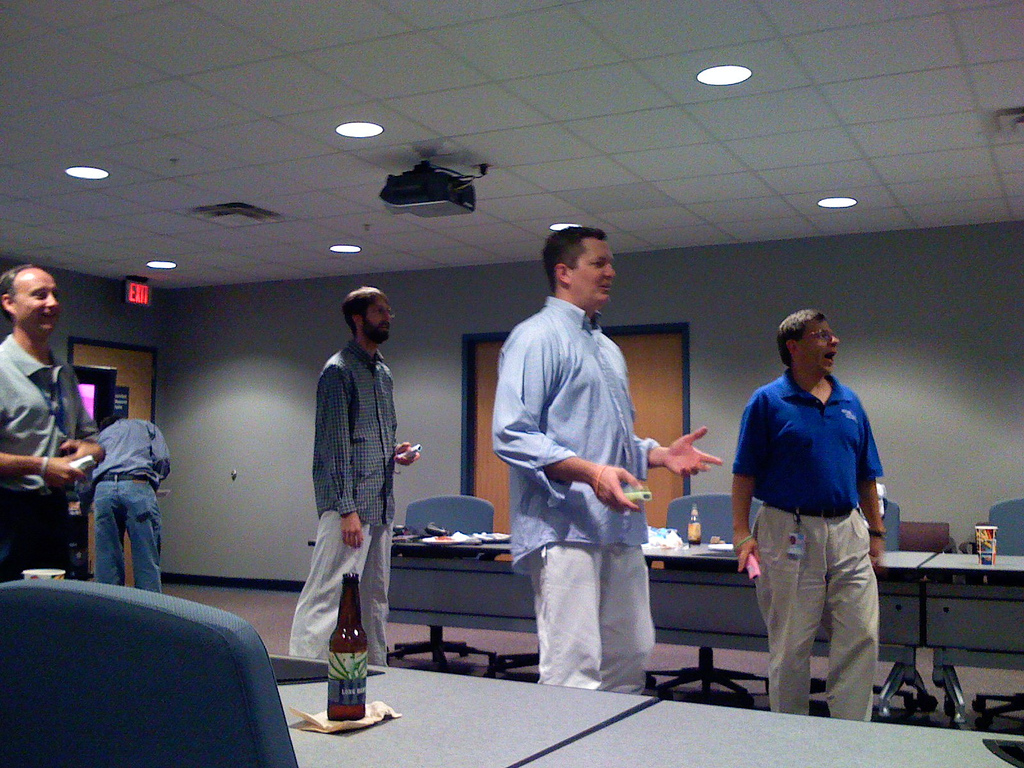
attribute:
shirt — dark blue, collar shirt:
[732, 376, 881, 517]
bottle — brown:
[324, 570, 364, 720]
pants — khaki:
[752, 508, 880, 717]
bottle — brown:
[325, 575, 368, 718]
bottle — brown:
[330, 575, 366, 718]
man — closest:
[90, 420, 170, 592]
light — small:
[697, 59, 756, 94]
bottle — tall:
[332, 564, 370, 716]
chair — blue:
[399, 488, 494, 530]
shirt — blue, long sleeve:
[498, 285, 658, 579]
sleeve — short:
[727, 381, 782, 485]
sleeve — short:
[847, 389, 887, 485]